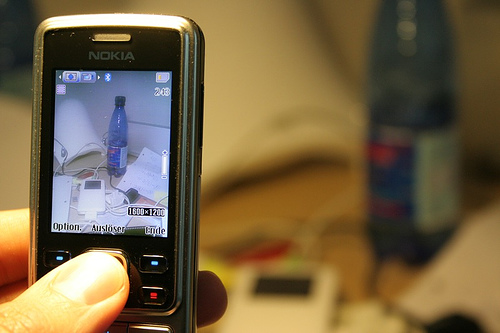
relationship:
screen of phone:
[52, 79, 172, 216] [4, 6, 214, 287]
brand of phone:
[90, 45, 148, 63] [4, 6, 214, 287]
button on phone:
[136, 248, 170, 276] [4, 6, 214, 287]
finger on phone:
[48, 252, 128, 307] [4, 6, 214, 287]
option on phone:
[51, 218, 162, 243] [4, 6, 214, 287]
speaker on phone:
[84, 23, 135, 58] [4, 6, 214, 287]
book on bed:
[204, 16, 337, 149] [251, 181, 341, 224]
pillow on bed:
[1, 29, 28, 68] [251, 181, 341, 224]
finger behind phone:
[48, 252, 128, 307] [4, 6, 214, 287]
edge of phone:
[170, 16, 210, 44] [4, 6, 214, 287]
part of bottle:
[407, 75, 424, 93] [322, 15, 472, 284]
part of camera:
[123, 93, 152, 123] [52, 79, 172, 216]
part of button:
[155, 256, 156, 262] [136, 248, 170, 276]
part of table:
[299, 184, 329, 191] [288, 177, 303, 187]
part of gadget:
[131, 75, 192, 151] [92, 91, 193, 173]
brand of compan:
[89, 52, 137, 62] [88, 51, 151, 66]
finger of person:
[48, 252, 128, 307] [11, 199, 130, 325]